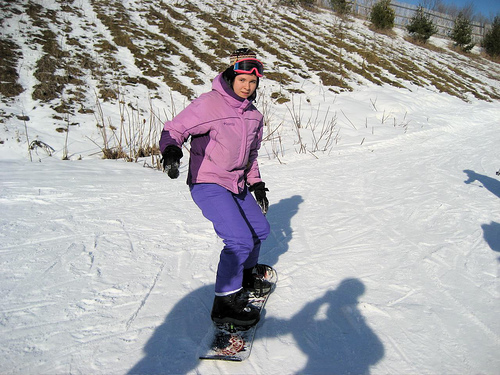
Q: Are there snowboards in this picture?
A: Yes, there is a snowboard.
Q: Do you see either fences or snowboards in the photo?
A: Yes, there is a snowboard.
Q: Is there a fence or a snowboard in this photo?
A: Yes, there is a snowboard.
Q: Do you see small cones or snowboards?
A: Yes, there is a small snowboard.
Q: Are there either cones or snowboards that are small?
A: Yes, the snowboard is small.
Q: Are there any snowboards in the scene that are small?
A: Yes, there is a small snowboard.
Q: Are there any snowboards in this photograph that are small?
A: Yes, there is a snowboard that is small.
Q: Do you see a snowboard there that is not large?
A: Yes, there is a small snowboard.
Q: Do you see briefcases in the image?
A: No, there are no briefcases.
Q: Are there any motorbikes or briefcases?
A: No, there are no briefcases or motorbikes.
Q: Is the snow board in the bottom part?
A: Yes, the snow board is in the bottom of the image.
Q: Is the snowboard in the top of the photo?
A: No, the snowboard is in the bottom of the image.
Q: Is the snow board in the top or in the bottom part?
A: The snow board is in the bottom of the image.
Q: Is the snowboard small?
A: Yes, the snowboard is small.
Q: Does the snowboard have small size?
A: Yes, the snowboard is small.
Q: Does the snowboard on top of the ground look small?
A: Yes, the snowboard is small.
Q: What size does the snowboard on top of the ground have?
A: The snowboard has small size.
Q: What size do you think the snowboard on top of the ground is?
A: The snowboard is small.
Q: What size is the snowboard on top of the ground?
A: The snowboard is small.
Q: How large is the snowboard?
A: The snowboard is small.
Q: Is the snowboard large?
A: No, the snowboard is small.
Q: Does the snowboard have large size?
A: No, the snowboard is small.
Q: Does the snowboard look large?
A: No, the snowboard is small.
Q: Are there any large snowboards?
A: No, there is a snowboard but it is small.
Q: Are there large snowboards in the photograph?
A: No, there is a snowboard but it is small.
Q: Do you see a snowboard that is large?
A: No, there is a snowboard but it is small.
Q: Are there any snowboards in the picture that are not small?
A: No, there is a snowboard but it is small.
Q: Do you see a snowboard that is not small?
A: No, there is a snowboard but it is small.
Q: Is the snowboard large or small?
A: The snowboard is small.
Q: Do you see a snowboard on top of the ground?
A: Yes, there is a snowboard on top of the ground.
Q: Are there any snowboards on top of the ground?
A: Yes, there is a snowboard on top of the ground.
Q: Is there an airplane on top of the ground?
A: No, there is a snowboard on top of the ground.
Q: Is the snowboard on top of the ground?
A: Yes, the snowboard is on top of the ground.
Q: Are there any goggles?
A: Yes, there are goggles.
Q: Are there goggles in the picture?
A: Yes, there are goggles.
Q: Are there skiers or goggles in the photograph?
A: Yes, there are goggles.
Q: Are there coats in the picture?
A: Yes, there is a coat.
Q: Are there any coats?
A: Yes, there is a coat.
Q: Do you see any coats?
A: Yes, there is a coat.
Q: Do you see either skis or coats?
A: Yes, there is a coat.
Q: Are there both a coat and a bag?
A: No, there is a coat but no bags.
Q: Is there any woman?
A: Yes, there is a woman.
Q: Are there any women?
A: Yes, there is a woman.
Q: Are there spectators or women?
A: Yes, there is a woman.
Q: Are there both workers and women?
A: No, there is a woman but no workers.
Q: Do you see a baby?
A: No, there are no babies.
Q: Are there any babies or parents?
A: No, there are no babies or parents.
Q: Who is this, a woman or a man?
A: This is a woman.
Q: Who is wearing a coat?
A: The woman is wearing a coat.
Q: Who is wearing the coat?
A: The woman is wearing a coat.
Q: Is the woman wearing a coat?
A: Yes, the woman is wearing a coat.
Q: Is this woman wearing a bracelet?
A: No, the woman is wearing a coat.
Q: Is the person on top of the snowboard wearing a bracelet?
A: No, the woman is wearing a coat.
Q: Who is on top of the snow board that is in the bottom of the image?
A: The woman is on top of the snow board.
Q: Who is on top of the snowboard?
A: The woman is on top of the snow board.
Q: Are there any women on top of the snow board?
A: Yes, there is a woman on top of the snow board.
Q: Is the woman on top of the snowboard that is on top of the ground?
A: Yes, the woman is on top of the snowboard.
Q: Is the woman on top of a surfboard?
A: No, the woman is on top of the snowboard.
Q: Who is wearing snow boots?
A: The woman is wearing snow boots.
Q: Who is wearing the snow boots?
A: The woman is wearing snow boots.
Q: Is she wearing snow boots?
A: Yes, the woman is wearing snow boots.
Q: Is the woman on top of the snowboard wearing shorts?
A: No, the woman is wearing snow boots.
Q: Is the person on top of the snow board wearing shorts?
A: No, the woman is wearing snow boots.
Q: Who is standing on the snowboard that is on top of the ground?
A: The woman is standing on the snowboard.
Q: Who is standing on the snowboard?
A: The woman is standing on the snowboard.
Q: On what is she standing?
A: The woman is standing on the snowboard.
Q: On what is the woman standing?
A: The woman is standing on the snowboard.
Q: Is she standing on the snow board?
A: Yes, the woman is standing on the snow board.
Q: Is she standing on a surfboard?
A: No, the woman is standing on the snow board.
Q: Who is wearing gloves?
A: The woman is wearing gloves.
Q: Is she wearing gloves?
A: Yes, the woman is wearing gloves.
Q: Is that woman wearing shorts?
A: No, the woman is wearing gloves.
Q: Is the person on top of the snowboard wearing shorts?
A: No, the woman is wearing gloves.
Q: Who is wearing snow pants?
A: The woman is wearing snow pants.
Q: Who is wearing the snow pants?
A: The woman is wearing snow pants.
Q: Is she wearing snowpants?
A: Yes, the woman is wearing snowpants.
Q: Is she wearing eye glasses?
A: No, the woman is wearing snowpants.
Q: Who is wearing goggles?
A: The woman is wearing goggles.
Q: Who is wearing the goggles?
A: The woman is wearing goggles.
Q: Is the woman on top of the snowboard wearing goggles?
A: Yes, the woman is wearing goggles.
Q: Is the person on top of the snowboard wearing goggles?
A: Yes, the woman is wearing goggles.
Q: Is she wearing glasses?
A: No, the woman is wearing goggles.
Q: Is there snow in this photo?
A: Yes, there is snow.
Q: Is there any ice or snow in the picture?
A: Yes, there is snow.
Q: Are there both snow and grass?
A: Yes, there are both snow and grass.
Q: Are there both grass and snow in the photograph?
A: Yes, there are both snow and grass.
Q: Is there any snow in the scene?
A: Yes, there is snow.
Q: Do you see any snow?
A: Yes, there is snow.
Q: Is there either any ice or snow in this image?
A: Yes, there is snow.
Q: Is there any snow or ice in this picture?
A: Yes, there is snow.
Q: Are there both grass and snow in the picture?
A: Yes, there are both snow and grass.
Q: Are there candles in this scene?
A: No, there are no candles.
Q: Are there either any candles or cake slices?
A: No, there are no candles or cake slices.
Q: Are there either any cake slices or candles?
A: No, there are no candles or cake slices.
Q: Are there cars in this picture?
A: No, there are no cars.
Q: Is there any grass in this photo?
A: Yes, there is grass.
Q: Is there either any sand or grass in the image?
A: Yes, there is grass.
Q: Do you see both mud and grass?
A: No, there is grass but no mud.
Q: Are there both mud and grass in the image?
A: No, there is grass but no mud.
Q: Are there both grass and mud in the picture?
A: No, there is grass but no mud.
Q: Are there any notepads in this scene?
A: No, there are no notepads.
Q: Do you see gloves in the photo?
A: Yes, there are gloves.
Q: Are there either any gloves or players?
A: Yes, there are gloves.